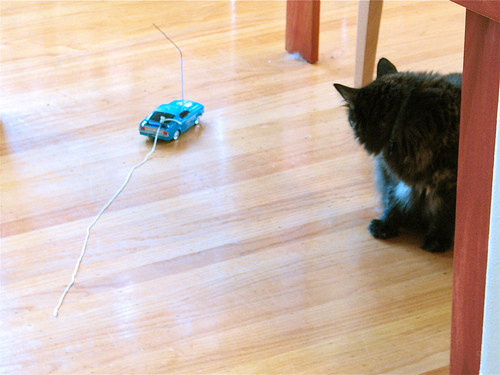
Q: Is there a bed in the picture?
A: No, there are no beds.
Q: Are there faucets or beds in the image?
A: No, there are no beds or faucets.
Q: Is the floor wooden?
A: Yes, the floor is wooden.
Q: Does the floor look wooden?
A: Yes, the floor is wooden.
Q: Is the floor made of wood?
A: Yes, the floor is made of wood.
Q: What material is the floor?
A: The floor is made of wood.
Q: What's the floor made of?
A: The floor is made of wood.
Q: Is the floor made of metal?
A: No, the floor is made of wood.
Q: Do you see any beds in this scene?
A: No, there are no beds.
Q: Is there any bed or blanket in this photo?
A: No, there are no beds or blankets.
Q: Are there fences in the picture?
A: No, there are no fences.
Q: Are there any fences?
A: No, there are no fences.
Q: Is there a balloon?
A: No, there are no balloons.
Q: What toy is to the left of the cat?
A: The toy is a toy car.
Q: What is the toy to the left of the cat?
A: The toy is a toy car.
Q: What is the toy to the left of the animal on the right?
A: The toy is a toy car.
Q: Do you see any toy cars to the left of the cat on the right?
A: Yes, there is a toy car to the left of the cat.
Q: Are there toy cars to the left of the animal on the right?
A: Yes, there is a toy car to the left of the cat.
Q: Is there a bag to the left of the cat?
A: No, there is a toy car to the left of the cat.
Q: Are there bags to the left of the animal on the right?
A: No, there is a toy car to the left of the cat.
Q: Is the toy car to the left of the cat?
A: Yes, the toy car is to the left of the cat.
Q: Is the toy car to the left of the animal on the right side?
A: Yes, the toy car is to the left of the cat.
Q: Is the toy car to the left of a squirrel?
A: No, the toy car is to the left of the cat.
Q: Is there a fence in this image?
A: No, there are no fences.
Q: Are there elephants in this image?
A: No, there are no elephants.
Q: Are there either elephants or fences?
A: No, there are no elephants or fences.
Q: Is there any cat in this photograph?
A: Yes, there is a cat.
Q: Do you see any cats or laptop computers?
A: Yes, there is a cat.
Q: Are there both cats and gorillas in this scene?
A: No, there is a cat but no gorillas.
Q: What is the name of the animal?
A: The animal is a cat.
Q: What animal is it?
A: The animal is a cat.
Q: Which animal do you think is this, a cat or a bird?
A: This is a cat.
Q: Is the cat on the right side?
A: Yes, the cat is on the right of the image.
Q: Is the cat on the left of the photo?
A: No, the cat is on the right of the image.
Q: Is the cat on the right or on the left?
A: The cat is on the right of the image.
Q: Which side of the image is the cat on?
A: The cat is on the right of the image.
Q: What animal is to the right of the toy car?
A: The animal is a cat.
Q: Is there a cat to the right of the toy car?
A: Yes, there is a cat to the right of the toy car.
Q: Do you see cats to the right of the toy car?
A: Yes, there is a cat to the right of the toy car.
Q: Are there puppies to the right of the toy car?
A: No, there is a cat to the right of the toy car.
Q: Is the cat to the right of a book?
A: No, the cat is to the right of the toy car.